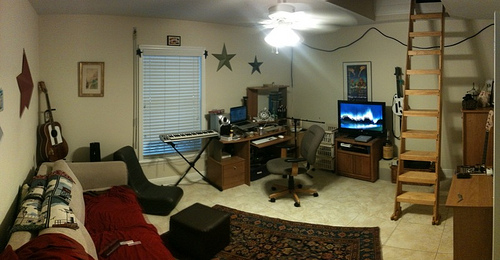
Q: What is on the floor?
A: A rug.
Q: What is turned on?
A: TV.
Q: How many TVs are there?
A: One.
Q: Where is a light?
A: On the ceiling.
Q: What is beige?
A: Couch.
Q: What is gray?
A: A chair.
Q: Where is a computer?
A: On the desk.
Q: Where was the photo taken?
A: In a basement.